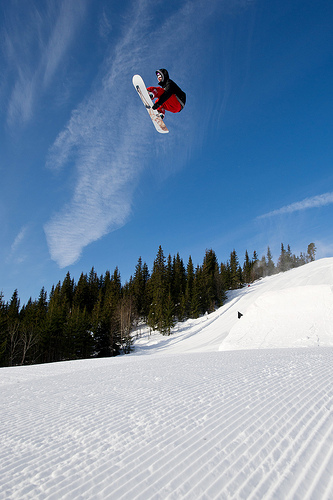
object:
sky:
[0, 0, 333, 315]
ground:
[0, 257, 333, 500]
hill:
[0, 243, 333, 367]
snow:
[0, 255, 333, 499]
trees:
[146, 244, 172, 335]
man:
[146, 67, 187, 120]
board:
[131, 73, 170, 134]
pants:
[146, 86, 182, 117]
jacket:
[152, 68, 187, 110]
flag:
[237, 311, 243, 320]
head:
[156, 68, 170, 86]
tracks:
[303, 444, 333, 500]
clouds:
[0, 0, 333, 312]